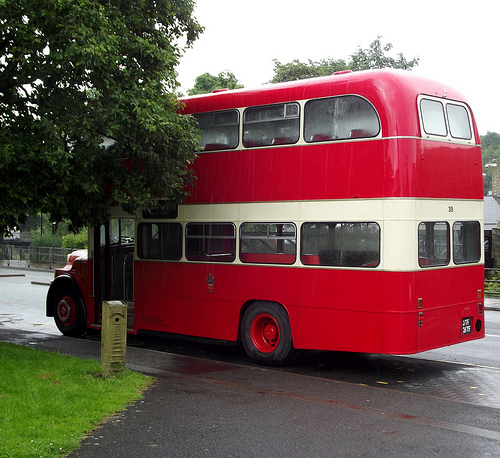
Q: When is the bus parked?
A: Daytime.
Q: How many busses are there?
A: One.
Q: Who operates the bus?
A: Driver.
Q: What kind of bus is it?
A: Double decker.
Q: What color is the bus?
A: Red and white.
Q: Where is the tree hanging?
A: Over the bus.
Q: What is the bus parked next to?
A: Sidewalk.